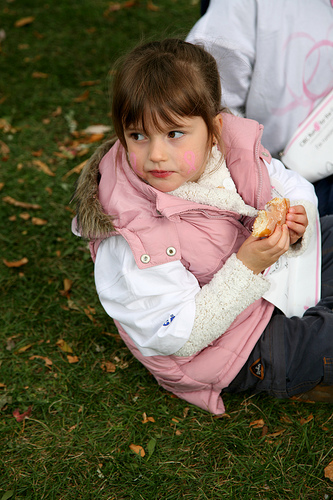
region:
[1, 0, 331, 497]
A green yard.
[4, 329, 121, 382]
Brown leaves on a yard.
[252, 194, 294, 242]
Half eaten donut.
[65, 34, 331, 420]
Young girl sitting on the grass.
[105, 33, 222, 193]
Little girl with her face painted.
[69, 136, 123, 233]
Fur on a girl's hood.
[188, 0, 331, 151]
Person wearing a white sweatshirt.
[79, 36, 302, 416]
Girl in a pink hooded vest.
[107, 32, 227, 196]
Young girl with brown eyes.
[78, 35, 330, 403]
Young girl eating a donut.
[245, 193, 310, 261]
child holding a piece of dough nut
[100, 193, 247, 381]
child wearing a pink jacker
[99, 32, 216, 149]
child with brown hair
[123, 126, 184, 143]
child with brown eyes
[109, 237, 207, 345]
child wearing a white shirt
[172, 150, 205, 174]
child with pink cheeks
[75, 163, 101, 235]
fur on a jacket collar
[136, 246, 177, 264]
buttons on a jacket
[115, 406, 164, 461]
leaves on the ground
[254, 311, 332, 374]
girl wearing gray pants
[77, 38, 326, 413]
girl sitting on grass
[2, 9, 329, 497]
autumn leaves on grass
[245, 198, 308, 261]
donut in two hands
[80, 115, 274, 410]
pink vest with hood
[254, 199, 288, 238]
half of glazed donut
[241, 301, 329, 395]
gray pants with emblem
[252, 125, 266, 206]
zipper on edge of vest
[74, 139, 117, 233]
fur on edge of hood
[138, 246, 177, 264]
metal studs on vest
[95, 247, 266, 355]
short sleeve over long sleeve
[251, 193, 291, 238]
a glazed donut in a girls hand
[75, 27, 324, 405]
a small girl sitting down on grass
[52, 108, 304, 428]
a pink vest on a child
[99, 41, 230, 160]
brown hair on a little girl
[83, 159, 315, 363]
a white shirt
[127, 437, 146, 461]
a brown leaf on the ground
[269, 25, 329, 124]
a pink female symbol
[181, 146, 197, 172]
a pink breast cancer ribbon tatoo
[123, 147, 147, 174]
a pink breast cancer ribbon tatoo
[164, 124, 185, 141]
a little girls eye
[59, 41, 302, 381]
girl sitting in the grass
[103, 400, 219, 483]
leaves in the grass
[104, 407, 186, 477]
the leaves are brown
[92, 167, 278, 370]
girl wearing a pink coat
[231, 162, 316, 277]
person is eating a sandwich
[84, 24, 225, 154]
girl has brown hair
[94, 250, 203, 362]
person wearing a white shirt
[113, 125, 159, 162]
girl has brown eyes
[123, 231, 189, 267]
buttons on the coat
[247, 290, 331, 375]
girl is wearing pants